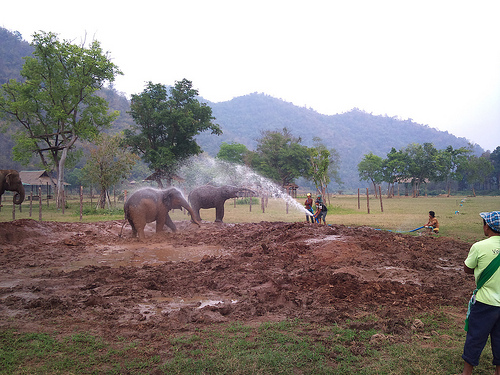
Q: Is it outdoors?
A: Yes, it is outdoors.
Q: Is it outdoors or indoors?
A: It is outdoors.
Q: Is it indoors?
A: No, it is outdoors.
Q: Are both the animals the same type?
A: Yes, all the animals are elephants.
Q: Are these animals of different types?
A: No, all the animals are elephants.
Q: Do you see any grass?
A: Yes, there is grass.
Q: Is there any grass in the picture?
A: Yes, there is grass.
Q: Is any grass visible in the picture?
A: Yes, there is grass.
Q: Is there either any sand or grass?
A: Yes, there is grass.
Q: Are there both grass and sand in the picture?
A: No, there is grass but no sand.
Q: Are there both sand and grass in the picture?
A: No, there is grass but no sand.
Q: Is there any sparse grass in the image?
A: Yes, there is sparse grass.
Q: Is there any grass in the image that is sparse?
A: Yes, there is grass that is sparse.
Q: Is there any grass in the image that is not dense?
A: Yes, there is sparse grass.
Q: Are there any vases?
A: No, there are no vases.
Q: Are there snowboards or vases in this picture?
A: No, there are no vases or snowboards.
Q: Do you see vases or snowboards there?
A: No, there are no vases or snowboards.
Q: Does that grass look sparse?
A: Yes, the grass is sparse.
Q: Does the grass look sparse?
A: Yes, the grass is sparse.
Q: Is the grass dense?
A: No, the grass is sparse.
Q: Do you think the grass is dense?
A: No, the grass is sparse.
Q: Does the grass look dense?
A: No, the grass is sparse.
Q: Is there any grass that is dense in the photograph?
A: No, there is grass but it is sparse.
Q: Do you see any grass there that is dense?
A: No, there is grass but it is sparse.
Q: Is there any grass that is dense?
A: No, there is grass but it is sparse.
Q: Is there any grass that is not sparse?
A: No, there is grass but it is sparse.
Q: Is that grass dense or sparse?
A: The grass is sparse.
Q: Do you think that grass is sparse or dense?
A: The grass is sparse.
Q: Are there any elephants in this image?
A: Yes, there is an elephant.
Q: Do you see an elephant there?
A: Yes, there is an elephant.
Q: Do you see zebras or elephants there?
A: Yes, there is an elephant.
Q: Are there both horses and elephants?
A: No, there is an elephant but no horses.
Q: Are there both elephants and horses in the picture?
A: No, there is an elephant but no horses.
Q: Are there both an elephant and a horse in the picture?
A: No, there is an elephant but no horses.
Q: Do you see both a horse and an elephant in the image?
A: No, there is an elephant but no horses.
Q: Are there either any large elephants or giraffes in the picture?
A: Yes, there is a large elephant.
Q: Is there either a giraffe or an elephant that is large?
A: Yes, the elephant is large.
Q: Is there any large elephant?
A: Yes, there is a large elephant.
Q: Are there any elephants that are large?
A: Yes, there is an elephant that is large.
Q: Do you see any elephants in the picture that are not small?
A: Yes, there is a large elephant.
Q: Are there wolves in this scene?
A: No, there are no wolves.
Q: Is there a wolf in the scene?
A: No, there are no wolves.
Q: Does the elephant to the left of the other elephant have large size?
A: Yes, the elephant is large.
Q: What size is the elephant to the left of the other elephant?
A: The elephant is large.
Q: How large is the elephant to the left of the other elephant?
A: The elephant is large.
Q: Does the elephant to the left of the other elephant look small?
A: No, the elephant is large.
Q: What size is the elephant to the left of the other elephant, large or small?
A: The elephant is large.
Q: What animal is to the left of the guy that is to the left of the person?
A: The animal is an elephant.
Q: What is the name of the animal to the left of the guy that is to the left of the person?
A: The animal is an elephant.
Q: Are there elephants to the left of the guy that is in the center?
A: Yes, there is an elephant to the left of the guy.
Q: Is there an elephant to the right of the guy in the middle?
A: No, the elephant is to the left of the guy.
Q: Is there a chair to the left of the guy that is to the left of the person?
A: No, there is an elephant to the left of the guy.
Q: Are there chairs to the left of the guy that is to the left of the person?
A: No, there is an elephant to the left of the guy.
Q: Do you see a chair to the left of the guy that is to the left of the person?
A: No, there is an elephant to the left of the guy.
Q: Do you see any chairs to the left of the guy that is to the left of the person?
A: No, there is an elephant to the left of the guy.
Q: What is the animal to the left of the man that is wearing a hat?
A: The animal is an elephant.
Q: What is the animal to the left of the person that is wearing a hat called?
A: The animal is an elephant.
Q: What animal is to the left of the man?
A: The animal is an elephant.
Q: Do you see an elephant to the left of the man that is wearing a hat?
A: Yes, there is an elephant to the left of the man.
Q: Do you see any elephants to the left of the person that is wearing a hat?
A: Yes, there is an elephant to the left of the man.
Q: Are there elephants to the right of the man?
A: No, the elephant is to the left of the man.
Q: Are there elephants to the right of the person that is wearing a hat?
A: No, the elephant is to the left of the man.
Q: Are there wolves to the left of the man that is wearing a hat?
A: No, there is an elephant to the left of the man.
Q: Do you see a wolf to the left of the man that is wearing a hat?
A: No, there is an elephant to the left of the man.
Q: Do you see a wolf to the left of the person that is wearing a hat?
A: No, there is an elephant to the left of the man.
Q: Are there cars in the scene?
A: No, there are no cars.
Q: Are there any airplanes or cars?
A: No, there are no cars or airplanes.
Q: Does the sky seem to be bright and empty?
A: Yes, the sky is bright and empty.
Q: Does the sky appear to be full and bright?
A: No, the sky is bright but empty.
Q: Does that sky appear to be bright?
A: Yes, the sky is bright.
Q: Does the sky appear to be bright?
A: Yes, the sky is bright.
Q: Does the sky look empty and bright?
A: Yes, the sky is empty and bright.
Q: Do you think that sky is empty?
A: Yes, the sky is empty.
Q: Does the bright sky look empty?
A: Yes, the sky is empty.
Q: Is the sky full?
A: No, the sky is empty.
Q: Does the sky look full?
A: No, the sky is empty.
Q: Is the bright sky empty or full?
A: The sky is empty.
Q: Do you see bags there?
A: Yes, there is a bag.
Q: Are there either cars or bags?
A: Yes, there is a bag.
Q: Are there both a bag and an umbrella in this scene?
A: No, there is a bag but no umbrellas.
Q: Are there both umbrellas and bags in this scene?
A: No, there is a bag but no umbrellas.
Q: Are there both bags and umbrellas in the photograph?
A: No, there is a bag but no umbrellas.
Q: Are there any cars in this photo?
A: No, there are no cars.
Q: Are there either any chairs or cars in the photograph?
A: No, there are no cars or chairs.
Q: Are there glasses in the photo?
A: No, there are no glasses.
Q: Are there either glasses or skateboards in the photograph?
A: No, there are no glasses or skateboards.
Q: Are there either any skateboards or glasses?
A: No, there are no glasses or skateboards.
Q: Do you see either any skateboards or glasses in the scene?
A: No, there are no glasses or skateboards.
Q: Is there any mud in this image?
A: Yes, there is mud.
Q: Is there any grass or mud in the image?
A: Yes, there is mud.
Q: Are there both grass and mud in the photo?
A: Yes, there are both mud and grass.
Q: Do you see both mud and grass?
A: Yes, there are both mud and grass.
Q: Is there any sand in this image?
A: No, there is no sand.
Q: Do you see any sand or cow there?
A: No, there are no sand or cows.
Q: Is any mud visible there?
A: Yes, there is mud.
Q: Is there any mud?
A: Yes, there is mud.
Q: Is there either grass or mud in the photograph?
A: Yes, there is mud.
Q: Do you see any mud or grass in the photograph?
A: Yes, there is mud.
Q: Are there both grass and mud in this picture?
A: Yes, there are both mud and grass.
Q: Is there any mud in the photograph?
A: Yes, there is mud.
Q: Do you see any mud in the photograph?
A: Yes, there is mud.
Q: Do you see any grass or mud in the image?
A: Yes, there is mud.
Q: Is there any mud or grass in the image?
A: Yes, there is mud.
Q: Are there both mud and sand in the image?
A: No, there is mud but no sand.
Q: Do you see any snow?
A: No, there is no snow.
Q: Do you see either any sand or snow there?
A: No, there are no snow or sand.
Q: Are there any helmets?
A: No, there are no helmets.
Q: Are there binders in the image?
A: No, there are no binders.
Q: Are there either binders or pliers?
A: No, there are no binders or pliers.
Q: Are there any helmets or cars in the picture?
A: No, there are no helmets or cars.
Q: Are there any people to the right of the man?
A: Yes, there is a person to the right of the man.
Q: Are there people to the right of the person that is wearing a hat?
A: Yes, there is a person to the right of the man.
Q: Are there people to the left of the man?
A: No, the person is to the right of the man.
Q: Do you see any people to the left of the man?
A: No, the person is to the right of the man.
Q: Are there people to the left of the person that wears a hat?
A: No, the person is to the right of the man.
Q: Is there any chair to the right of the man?
A: No, there is a person to the right of the man.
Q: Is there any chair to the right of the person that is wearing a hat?
A: No, there is a person to the right of the man.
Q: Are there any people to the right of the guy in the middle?
A: Yes, there is a person to the right of the guy.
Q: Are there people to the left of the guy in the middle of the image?
A: No, the person is to the right of the guy.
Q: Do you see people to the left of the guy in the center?
A: No, the person is to the right of the guy.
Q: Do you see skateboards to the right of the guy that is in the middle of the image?
A: No, there is a person to the right of the guy.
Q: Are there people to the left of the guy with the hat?
A: Yes, there is a person to the left of the guy.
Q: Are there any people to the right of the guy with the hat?
A: No, the person is to the left of the guy.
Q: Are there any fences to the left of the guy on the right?
A: No, there is a person to the left of the guy.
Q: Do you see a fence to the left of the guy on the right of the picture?
A: No, there is a person to the left of the guy.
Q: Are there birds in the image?
A: No, there are no birds.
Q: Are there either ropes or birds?
A: No, there are no birds or ropes.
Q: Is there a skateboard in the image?
A: No, there are no skateboards.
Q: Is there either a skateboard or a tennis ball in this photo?
A: No, there are no skateboards or tennis balls.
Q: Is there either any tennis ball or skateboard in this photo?
A: No, there are no skateboards or tennis balls.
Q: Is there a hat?
A: Yes, there is a hat.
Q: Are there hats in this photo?
A: Yes, there is a hat.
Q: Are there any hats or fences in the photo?
A: Yes, there is a hat.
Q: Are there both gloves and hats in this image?
A: No, there is a hat but no gloves.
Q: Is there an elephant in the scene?
A: Yes, there is an elephant.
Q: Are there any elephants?
A: Yes, there is an elephant.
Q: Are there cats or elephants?
A: Yes, there is an elephant.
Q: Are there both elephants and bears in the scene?
A: No, there is an elephant but no bears.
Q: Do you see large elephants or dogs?
A: Yes, there is a large elephant.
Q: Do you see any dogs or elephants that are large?
A: Yes, the elephant is large.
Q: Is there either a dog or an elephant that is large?
A: Yes, the elephant is large.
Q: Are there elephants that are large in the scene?
A: Yes, there is a large elephant.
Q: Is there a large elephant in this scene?
A: Yes, there is a large elephant.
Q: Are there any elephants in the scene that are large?
A: Yes, there is an elephant that is large.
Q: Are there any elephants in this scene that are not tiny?
A: Yes, there is a large elephant.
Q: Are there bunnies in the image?
A: No, there are no bunnies.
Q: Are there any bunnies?
A: No, there are no bunnies.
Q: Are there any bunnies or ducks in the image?
A: No, there are no bunnies or ducks.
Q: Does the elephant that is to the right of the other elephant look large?
A: Yes, the elephant is large.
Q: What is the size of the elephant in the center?
A: The elephant is large.